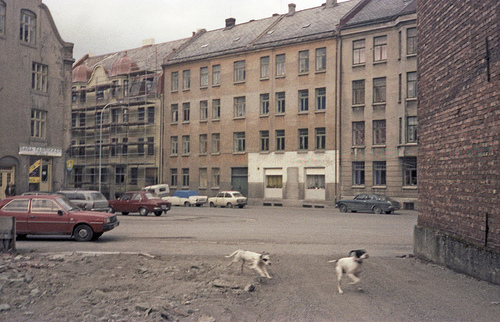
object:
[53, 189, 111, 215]
car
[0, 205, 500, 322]
street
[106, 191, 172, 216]
red car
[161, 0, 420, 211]
building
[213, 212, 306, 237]
center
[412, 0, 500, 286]
brick wall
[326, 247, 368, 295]
dogs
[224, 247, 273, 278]
dogs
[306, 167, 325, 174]
white section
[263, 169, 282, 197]
garage door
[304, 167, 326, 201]
garage door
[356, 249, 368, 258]
face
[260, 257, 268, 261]
eye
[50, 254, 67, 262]
stone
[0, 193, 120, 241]
car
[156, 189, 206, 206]
car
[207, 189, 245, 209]
car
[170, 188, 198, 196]
top